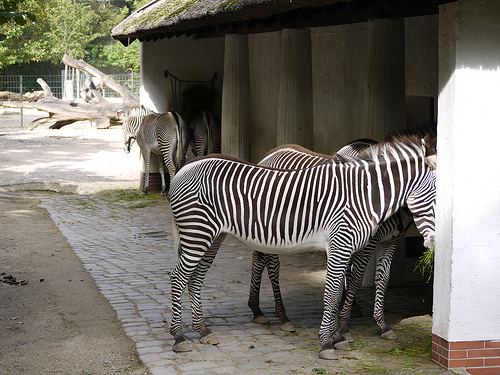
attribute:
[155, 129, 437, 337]
zebras — standing, three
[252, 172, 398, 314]
zebra — striped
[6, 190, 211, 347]
ground — unpaved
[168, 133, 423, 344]
stripes — black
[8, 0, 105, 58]
leaves — green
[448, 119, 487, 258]
wall — white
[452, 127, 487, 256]
wall — brick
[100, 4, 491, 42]
roof — dirty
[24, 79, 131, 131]
wood — drift, dead, large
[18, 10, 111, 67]
tree — green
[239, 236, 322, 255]
belly — white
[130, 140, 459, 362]
zebra — striped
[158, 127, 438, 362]
zebra — striped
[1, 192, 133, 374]
paved road — small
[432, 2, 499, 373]
pillar — cement, white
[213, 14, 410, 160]
columns — three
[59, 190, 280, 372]
walkway — cobbled